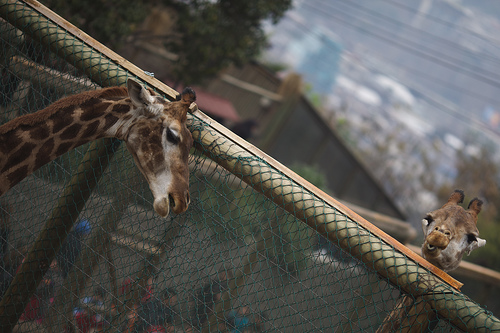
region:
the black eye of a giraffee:
[163, 125, 183, 147]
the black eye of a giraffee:
[424, 212, 434, 227]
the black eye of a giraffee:
[467, 229, 478, 243]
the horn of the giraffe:
[170, 88, 195, 113]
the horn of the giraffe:
[450, 187, 464, 203]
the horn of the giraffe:
[467, 196, 483, 216]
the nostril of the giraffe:
[433, 223, 439, 233]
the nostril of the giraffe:
[443, 229, 450, 238]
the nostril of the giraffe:
[181, 190, 191, 203]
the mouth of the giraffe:
[425, 239, 439, 253]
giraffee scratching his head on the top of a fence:
[7, 75, 201, 222]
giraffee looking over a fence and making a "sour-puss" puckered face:
[416, 187, 491, 271]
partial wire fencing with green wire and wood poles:
[8, 17, 488, 325]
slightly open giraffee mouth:
[163, 189, 178, 220]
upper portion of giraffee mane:
[3, 82, 132, 135]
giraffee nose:
[428, 224, 454, 243]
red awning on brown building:
[161, 77, 239, 122]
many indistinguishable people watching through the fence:
[20, 217, 275, 328]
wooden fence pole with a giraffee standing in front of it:
[4, 93, 161, 328]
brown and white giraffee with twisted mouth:
[416, 186, 490, 274]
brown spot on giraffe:
[112, 100, 129, 117]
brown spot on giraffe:
[80, 102, 112, 119]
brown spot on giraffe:
[102, 111, 120, 131]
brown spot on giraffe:
[82, 119, 101, 138]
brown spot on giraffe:
[53, 140, 72, 152]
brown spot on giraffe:
[60, 123, 79, 138]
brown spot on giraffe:
[50, 108, 75, 130]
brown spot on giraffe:
[27, 122, 52, 140]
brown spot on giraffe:
[8, 165, 30, 187]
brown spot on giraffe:
[3, 139, 33, 168]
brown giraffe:
[8, 68, 215, 239]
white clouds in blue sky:
[335, 38, 387, 79]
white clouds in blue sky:
[388, 69, 475, 111]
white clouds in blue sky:
[300, 93, 374, 120]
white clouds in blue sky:
[391, 118, 433, 153]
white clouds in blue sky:
[395, 29, 456, 59]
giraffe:
[18, 66, 195, 210]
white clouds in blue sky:
[384, 51, 454, 122]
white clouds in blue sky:
[375, 16, 439, 84]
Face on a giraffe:
[413, 189, 483, 269]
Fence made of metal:
[241, 224, 328, 311]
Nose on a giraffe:
[424, 224, 453, 254]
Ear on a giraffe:
[122, 74, 159, 119]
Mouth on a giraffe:
[138, 177, 198, 219]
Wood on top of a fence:
[366, 224, 453, 285]